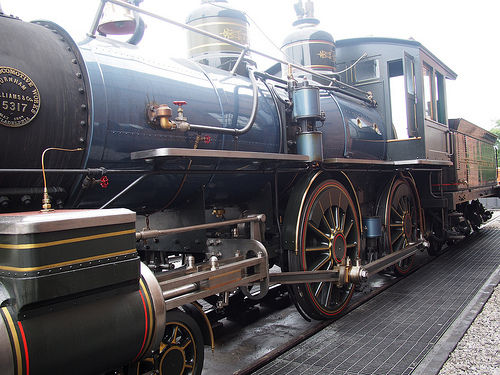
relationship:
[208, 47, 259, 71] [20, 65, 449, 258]
engine of train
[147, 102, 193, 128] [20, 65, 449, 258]
bell on train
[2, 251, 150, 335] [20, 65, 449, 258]
piston on train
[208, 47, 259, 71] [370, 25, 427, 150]
engine on door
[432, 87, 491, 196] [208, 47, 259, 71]
car behind engine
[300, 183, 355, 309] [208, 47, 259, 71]
wheel on engine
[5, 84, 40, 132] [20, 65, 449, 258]
nameplate on train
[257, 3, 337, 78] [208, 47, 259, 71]
stock on engine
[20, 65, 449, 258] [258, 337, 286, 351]
train on track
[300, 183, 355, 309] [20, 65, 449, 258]
wheel of train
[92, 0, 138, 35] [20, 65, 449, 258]
tank on train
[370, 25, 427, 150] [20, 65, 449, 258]
door on train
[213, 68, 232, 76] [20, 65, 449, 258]
fuel on train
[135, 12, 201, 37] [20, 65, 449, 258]
pipe on train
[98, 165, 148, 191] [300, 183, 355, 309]
bolt on wheel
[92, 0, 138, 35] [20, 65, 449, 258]
tank of train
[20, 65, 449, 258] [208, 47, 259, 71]
train has engine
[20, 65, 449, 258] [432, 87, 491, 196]
train pulling car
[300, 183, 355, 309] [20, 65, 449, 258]
wheel on train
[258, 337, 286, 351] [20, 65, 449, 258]
track on train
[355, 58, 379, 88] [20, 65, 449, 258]
window on train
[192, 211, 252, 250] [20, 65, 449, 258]
rivet on train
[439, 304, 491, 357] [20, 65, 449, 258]
walkway near train